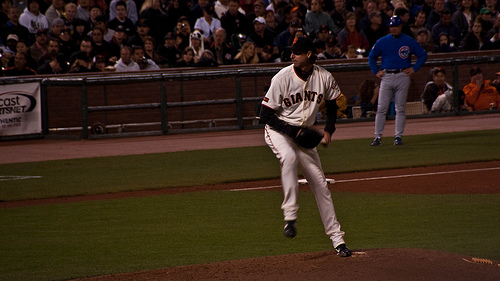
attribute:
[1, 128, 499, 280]
ground — here, green, treamed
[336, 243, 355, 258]
shoe — here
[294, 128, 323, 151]
glove — black, here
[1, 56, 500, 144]
fence — here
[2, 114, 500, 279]
field — here, green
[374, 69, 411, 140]
trouser — here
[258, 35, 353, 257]
player — here, standing, brown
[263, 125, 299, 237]
leg — up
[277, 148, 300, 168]
knee — bent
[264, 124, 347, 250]
trouser — white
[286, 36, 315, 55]
cap — black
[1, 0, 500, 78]
people — here, watching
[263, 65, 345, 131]
jersey — here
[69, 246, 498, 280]
mound — here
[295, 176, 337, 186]
base — white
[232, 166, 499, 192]
line — white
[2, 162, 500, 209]
path — brown, here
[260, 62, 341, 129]
shirt — white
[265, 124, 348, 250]
pants — white